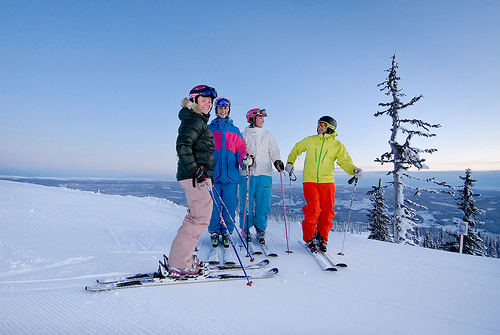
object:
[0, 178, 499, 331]
snow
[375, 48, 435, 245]
tree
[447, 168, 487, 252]
tree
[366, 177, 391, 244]
tree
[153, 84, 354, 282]
group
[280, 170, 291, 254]
ski-pole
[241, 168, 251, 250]
ski-pole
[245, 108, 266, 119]
helmet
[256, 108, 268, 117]
goggles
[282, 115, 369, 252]
man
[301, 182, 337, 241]
pants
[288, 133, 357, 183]
jacket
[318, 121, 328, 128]
goggles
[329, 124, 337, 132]
straps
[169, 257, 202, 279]
boots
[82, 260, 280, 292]
ski's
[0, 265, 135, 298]
marks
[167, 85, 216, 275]
woman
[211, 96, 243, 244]
woman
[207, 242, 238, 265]
ski's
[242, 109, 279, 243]
woman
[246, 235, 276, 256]
ski's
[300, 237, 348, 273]
ski's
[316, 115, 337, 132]
helmet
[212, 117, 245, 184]
jacket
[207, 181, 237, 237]
pants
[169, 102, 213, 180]
jacket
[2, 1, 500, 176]
sky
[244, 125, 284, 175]
jacket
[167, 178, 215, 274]
pants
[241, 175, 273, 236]
pants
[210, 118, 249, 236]
blue